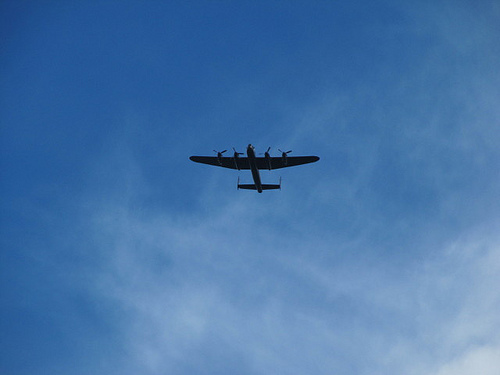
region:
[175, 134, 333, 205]
plane in the sky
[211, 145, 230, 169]
engine on a plane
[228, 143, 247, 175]
engine on a plane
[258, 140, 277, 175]
engine on a plane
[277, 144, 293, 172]
engine on a plane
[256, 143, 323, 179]
wing on a plane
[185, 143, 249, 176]
wing on a plane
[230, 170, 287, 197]
tail on a plane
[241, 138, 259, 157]
nose of a plane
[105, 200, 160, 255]
blue cloud in sky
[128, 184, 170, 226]
blue cloud in sky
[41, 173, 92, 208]
blue cloud in sky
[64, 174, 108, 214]
blue cloud in sky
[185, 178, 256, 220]
blue cloud in sky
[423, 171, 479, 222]
blue cloud in sky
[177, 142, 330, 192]
a jet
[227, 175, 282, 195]
tail of the jet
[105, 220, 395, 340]
the white clouds in the sky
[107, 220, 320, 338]
the clouds are white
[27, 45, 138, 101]
the sky is clear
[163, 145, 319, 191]
the jet is flying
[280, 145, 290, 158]
propeller on the jet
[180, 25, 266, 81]
the bright blue sky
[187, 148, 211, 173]
wing of the jet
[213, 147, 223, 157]
Far right propeller on a plane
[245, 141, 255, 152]
The nose of an airplane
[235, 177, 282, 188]
Tail of a fighter plane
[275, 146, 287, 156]
Far left propeller on an aircraft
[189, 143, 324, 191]
A big airplane in the sky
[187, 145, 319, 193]
A plane in the sky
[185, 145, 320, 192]
A plane with four propellers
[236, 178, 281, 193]
The back tail of an aircraft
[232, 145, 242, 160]
First propeller to the right on an airplane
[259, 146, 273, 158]
First propeller to the left on an airplane